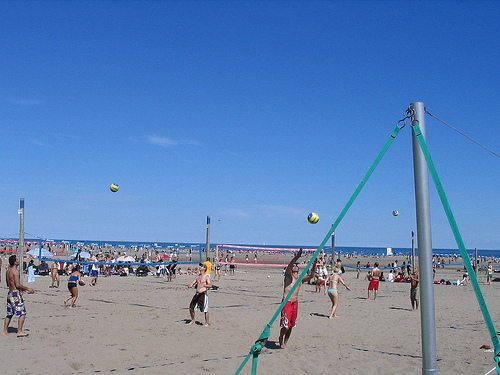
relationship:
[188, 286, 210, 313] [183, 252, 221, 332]
shorts on man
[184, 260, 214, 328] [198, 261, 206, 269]
man wearing a hat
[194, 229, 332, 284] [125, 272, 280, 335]
net on beach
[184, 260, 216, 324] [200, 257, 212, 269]
man wearing hat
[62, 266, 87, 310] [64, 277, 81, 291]
person wearing bikini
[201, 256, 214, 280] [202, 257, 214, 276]
man wearing shirt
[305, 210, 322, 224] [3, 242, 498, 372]
volleyball net on beach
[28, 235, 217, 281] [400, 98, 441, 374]
net on pole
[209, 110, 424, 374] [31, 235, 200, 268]
green strap on net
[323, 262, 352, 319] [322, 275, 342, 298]
person in bikini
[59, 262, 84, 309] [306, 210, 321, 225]
person playing volleyball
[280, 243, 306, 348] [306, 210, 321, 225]
person playing volleyball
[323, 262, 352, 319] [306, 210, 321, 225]
person playing volleyball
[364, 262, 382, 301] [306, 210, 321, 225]
people playing volleyball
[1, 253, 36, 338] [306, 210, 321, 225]
people playing volleyball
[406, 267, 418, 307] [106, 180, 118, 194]
people playing volleyball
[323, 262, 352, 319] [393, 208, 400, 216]
person playing volleyball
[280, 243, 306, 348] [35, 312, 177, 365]
person on beach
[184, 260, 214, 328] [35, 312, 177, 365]
man on beach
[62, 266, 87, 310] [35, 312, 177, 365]
person on beach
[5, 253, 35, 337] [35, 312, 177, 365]
people on beach